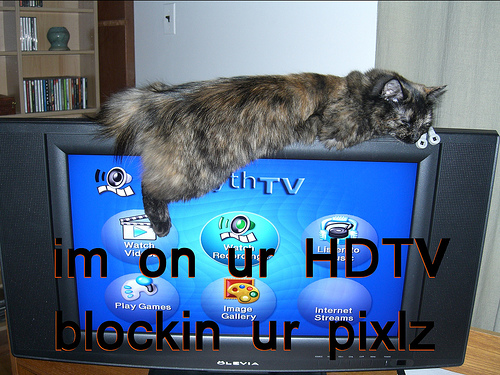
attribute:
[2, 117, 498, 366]
television — black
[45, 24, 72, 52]
knick knack — green, ceramic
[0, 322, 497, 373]
wood flooring — hardwood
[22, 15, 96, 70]
bowl — craft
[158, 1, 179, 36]
light switch — wall mounted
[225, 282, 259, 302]
icon — paint, palette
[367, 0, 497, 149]
curtain — white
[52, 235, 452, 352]
words — black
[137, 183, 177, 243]
cat foot — hanging